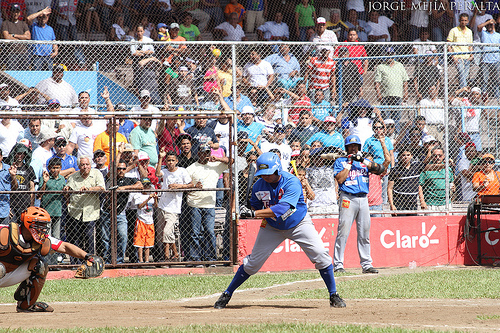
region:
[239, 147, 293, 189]
Blue and white baseball helmet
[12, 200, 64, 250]
Orange and black umpire helmet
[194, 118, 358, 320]
Baseball player waiting to swing bat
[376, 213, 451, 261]
White Claro logo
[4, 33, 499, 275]
Silver chain link fence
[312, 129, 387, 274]
Man waiting to play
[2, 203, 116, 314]
Catcher waiting for the ball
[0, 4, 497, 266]
Large audience watching game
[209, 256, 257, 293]
Blue socks on baseball player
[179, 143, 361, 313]
Man wearing baseball uniform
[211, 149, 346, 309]
a batter preparing to swing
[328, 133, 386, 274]
a baseball player standing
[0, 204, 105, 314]
a baseball catcher in a crouch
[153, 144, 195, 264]
a boy holding his hand up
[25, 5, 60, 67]
a man shielding his face from the sun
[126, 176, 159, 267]
a boy in orange shorts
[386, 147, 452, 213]
a man holding his left arm out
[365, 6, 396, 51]
a man sitting down, leaning on his right arm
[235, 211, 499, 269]
a low wall with writing on it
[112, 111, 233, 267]
a gate in a chain link fence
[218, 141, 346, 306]
Man playing baseball.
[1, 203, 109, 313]
Catcher behind the batter.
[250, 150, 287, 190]
Blue helmet on the man.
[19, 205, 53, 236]
Orange helmet on the man.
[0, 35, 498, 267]
Chain link fence in the background.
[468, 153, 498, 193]
Lady in an orange shirt.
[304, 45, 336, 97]
Striped shirt on the man.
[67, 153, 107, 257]
Man leaning on the fence.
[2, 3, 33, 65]
Man wearing blue hat.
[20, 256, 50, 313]
Orange shin guards on leg.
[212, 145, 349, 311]
A man playing baseball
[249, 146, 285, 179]
A helmet is blue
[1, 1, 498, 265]
Spectators watching the game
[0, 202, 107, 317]
A catcher is crouched down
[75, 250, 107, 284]
A black leather glove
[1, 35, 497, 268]
A fence in front of the spectators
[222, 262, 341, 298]
A pair of blue socks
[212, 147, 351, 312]
Player holding a baseball bat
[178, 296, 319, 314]
Shadow on the dirt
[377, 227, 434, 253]
The word "Claro" on a sign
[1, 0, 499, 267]
Spectators behind a fence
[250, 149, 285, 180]
A blue colored helmet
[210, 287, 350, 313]
A pair of black sneakers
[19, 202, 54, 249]
Orange helmet and face mask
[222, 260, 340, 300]
Two socks are blue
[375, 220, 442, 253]
"Claro" is written on red sign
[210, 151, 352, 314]
Batter is holding a bat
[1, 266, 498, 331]
Brown dirt on the baseball field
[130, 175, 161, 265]
Kid is wearing orange shorts